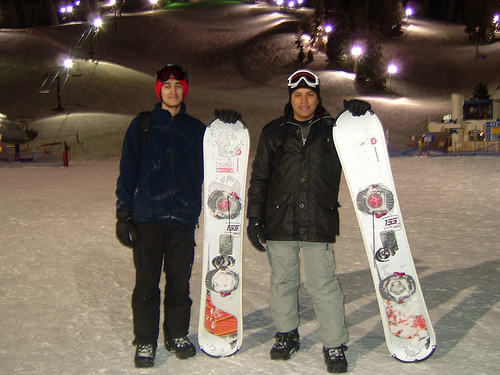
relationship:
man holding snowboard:
[115, 62, 242, 367] [205, 108, 251, 364]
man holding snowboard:
[244, 67, 355, 368] [348, 114, 435, 367]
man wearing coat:
[244, 67, 355, 368] [254, 130, 334, 224]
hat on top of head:
[149, 70, 190, 87] [150, 68, 196, 111]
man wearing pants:
[244, 67, 355, 368] [274, 237, 348, 347]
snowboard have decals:
[205, 108, 251, 364] [212, 188, 239, 262]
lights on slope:
[81, 16, 107, 27] [43, 4, 104, 110]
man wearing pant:
[125, 53, 199, 365] [128, 231, 194, 340]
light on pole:
[342, 43, 368, 61] [348, 57, 359, 83]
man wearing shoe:
[244, 67, 355, 368] [272, 327, 300, 365]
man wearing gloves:
[244, 67, 355, 368] [245, 216, 272, 255]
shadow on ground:
[340, 260, 488, 350] [18, 192, 496, 374]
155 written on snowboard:
[223, 221, 244, 235] [205, 108, 251, 364]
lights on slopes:
[81, 16, 107, 27] [26, 22, 98, 173]